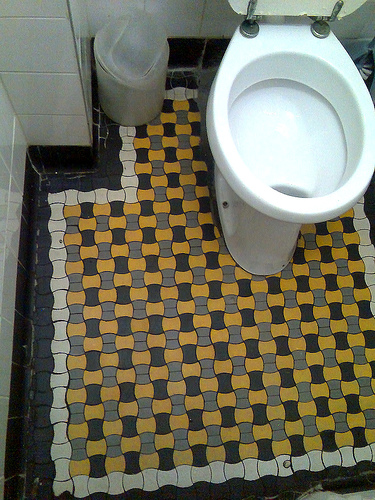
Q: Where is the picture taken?
A: A bathroom.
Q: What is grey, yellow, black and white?
A: Floor tile.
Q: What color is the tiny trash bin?
A: Green.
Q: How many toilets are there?
A: One.